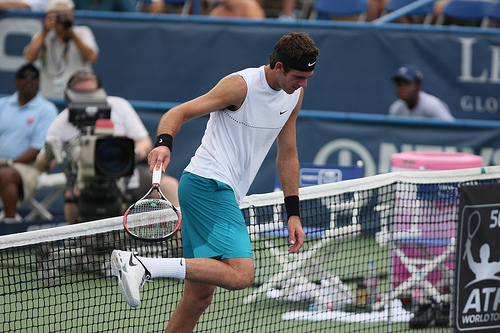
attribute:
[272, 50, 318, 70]
headband — black, sports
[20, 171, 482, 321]
net — tennis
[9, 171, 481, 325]
tennis net — black, white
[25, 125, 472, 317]
court — tennis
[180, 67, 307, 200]
tshirt — white, vest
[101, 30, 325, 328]
player — tennis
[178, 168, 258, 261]
shorts — green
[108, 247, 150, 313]
shoes — nike, white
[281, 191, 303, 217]
wristband — black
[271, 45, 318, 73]
bandana — black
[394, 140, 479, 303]
cooler — large, pink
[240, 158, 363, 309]
chair — blue, white, folder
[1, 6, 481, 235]
barriers — blue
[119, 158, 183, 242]
racket — white, orange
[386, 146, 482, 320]
bucket — pink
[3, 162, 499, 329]
net — black, mesh, tennis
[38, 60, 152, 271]
operator — video camera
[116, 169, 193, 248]
racquet — tennis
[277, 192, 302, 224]
band — black, wrist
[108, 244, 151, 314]
shoe — white, tennis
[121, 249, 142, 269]
check — black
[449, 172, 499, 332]
sign — black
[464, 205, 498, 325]
lettering — white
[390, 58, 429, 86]
cap — blue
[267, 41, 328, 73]
band — black, sweat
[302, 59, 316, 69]
check — white